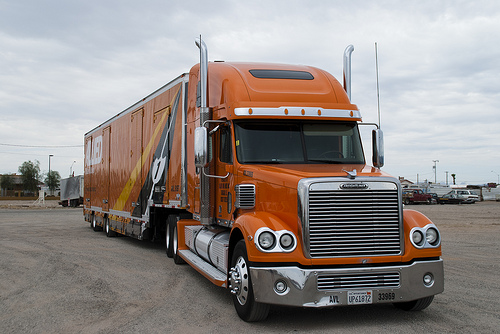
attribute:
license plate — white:
[346, 287, 375, 307]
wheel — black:
[98, 208, 113, 237]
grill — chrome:
[305, 176, 405, 257]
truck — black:
[72, 57, 433, 260]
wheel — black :
[87, 208, 100, 228]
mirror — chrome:
[171, 117, 242, 181]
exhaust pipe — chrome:
[343, 48, 361, 99]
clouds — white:
[385, 9, 499, 159]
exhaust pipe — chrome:
[193, 38, 211, 220]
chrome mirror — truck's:
[192, 117, 207, 174]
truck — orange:
[161, 52, 328, 278]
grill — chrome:
[284, 154, 411, 264]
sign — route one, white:
[151, 155, 167, 183]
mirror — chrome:
[192, 117, 231, 179]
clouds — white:
[24, 12, 80, 49]